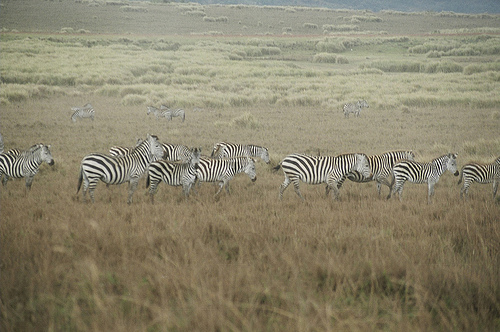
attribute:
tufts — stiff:
[140, 171, 153, 188]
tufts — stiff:
[71, 157, 82, 201]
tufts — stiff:
[207, 140, 219, 162]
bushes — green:
[4, 6, 498, 111]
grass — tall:
[186, 215, 452, 307]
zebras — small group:
[63, 102, 194, 125]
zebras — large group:
[0, 133, 499, 203]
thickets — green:
[12, 22, 494, 114]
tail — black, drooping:
[73, 171, 85, 197]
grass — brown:
[260, 203, 401, 292]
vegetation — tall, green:
[3, 2, 499, 130]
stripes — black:
[302, 157, 325, 182]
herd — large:
[84, 139, 449, 193]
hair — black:
[74, 171, 84, 193]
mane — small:
[126, 133, 153, 152]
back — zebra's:
[72, 143, 156, 168]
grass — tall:
[283, 226, 422, 308]